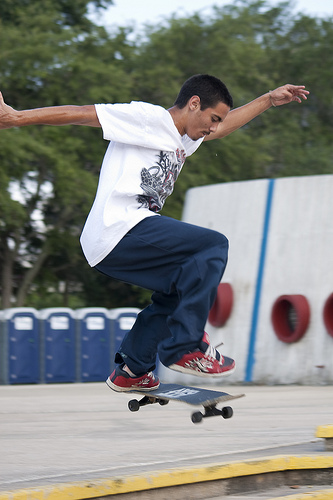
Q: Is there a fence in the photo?
A: No, there are no fences.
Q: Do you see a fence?
A: No, there are no fences.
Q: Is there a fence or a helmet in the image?
A: No, there are no fences or helmets.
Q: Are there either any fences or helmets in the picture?
A: No, there are no fences or helmets.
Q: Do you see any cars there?
A: No, there are no cars.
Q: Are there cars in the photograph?
A: No, there are no cars.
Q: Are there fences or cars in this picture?
A: No, there are no cars or fences.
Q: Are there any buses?
A: No, there are no buses.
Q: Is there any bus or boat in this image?
A: No, there are no buses or boats.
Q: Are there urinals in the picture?
A: No, there are no urinals.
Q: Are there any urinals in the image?
A: No, there are no urinals.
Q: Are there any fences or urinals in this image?
A: No, there are no urinals or fences.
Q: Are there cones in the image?
A: No, there are no cones.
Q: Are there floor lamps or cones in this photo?
A: No, there are no cones or floor lamps.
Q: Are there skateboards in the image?
A: Yes, there is a skateboard.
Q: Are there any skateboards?
A: Yes, there is a skateboard.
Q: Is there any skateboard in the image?
A: Yes, there is a skateboard.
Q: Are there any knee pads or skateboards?
A: Yes, there is a skateboard.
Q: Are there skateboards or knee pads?
A: Yes, there is a skateboard.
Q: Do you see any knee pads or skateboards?
A: Yes, there is a skateboard.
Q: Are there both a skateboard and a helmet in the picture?
A: No, there is a skateboard but no helmets.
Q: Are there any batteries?
A: No, there are no batteries.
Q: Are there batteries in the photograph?
A: No, there are no batteries.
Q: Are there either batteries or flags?
A: No, there are no batteries or flags.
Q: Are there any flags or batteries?
A: No, there are no batteries or flags.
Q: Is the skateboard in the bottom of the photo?
A: Yes, the skateboard is in the bottom of the image.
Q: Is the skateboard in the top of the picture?
A: No, the skateboard is in the bottom of the image.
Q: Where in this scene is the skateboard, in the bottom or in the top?
A: The skateboard is in the bottom of the image.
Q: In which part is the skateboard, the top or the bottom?
A: The skateboard is in the bottom of the image.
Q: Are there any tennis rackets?
A: No, there are no tennis rackets.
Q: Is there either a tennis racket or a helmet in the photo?
A: No, there are no rackets or helmets.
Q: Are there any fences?
A: No, there are no fences.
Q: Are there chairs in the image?
A: No, there are no chairs.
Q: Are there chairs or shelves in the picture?
A: No, there are no chairs or shelves.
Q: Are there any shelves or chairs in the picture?
A: No, there are no chairs or shelves.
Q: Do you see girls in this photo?
A: No, there are no girls.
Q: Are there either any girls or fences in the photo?
A: No, there are no girls or fences.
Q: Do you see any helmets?
A: No, there are no helmets.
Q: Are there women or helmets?
A: No, there are no helmets or women.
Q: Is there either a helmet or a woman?
A: No, there are no helmets or women.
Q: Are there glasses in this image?
A: No, there are no glasses.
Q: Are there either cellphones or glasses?
A: No, there are no glasses or cellphones.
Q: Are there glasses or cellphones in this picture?
A: No, there are no glasses or cellphones.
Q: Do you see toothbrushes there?
A: No, there are no toothbrushes.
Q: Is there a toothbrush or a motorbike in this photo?
A: No, there are no toothbrushes or motorcycles.